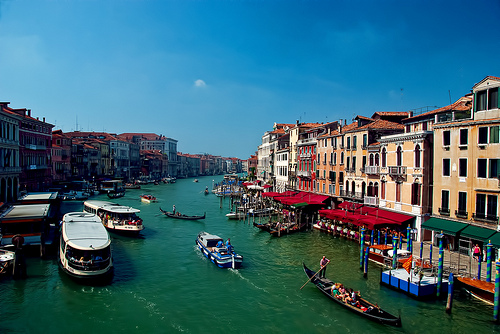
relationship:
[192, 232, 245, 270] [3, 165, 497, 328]
boat on water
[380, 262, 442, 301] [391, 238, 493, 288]
boat near dock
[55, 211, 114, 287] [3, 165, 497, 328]
boat on water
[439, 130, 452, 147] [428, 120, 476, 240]
window on building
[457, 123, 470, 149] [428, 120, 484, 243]
window on building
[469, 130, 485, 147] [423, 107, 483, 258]
window on building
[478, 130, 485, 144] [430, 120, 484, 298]
window on building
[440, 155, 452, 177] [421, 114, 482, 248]
window on building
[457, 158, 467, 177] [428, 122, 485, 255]
window on building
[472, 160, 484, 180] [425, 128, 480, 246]
window on building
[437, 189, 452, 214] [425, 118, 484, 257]
window on building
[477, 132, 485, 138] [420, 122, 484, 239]
window on building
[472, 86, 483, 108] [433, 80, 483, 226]
window on building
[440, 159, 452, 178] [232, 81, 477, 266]
window on building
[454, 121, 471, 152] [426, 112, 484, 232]
window on building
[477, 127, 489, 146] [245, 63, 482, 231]
window on building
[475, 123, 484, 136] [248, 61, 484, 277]
window on building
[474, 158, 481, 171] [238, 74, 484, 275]
window on building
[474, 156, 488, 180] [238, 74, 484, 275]
window on building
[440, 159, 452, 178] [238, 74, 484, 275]
window on building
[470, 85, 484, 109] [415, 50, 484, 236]
window on building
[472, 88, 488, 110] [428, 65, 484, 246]
window on building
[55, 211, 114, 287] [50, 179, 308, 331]
boat on water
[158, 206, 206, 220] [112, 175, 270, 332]
boat on water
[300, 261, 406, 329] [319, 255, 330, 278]
boat carrying man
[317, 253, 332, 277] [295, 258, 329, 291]
man holding paddle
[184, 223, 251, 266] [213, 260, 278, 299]
boat leaving trail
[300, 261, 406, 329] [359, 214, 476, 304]
boat near dock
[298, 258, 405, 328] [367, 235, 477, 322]
boat near dock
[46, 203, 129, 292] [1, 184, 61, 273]
boat near dock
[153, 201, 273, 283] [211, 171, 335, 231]
boat by dock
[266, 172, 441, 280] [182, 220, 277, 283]
dock by boat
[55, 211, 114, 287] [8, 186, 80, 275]
boat by dock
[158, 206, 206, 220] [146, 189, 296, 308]
boat on water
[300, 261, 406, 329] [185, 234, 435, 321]
boat on water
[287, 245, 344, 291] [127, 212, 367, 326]
paddle on water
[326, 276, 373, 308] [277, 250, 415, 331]
people on gondola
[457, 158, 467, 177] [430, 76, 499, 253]
window on building